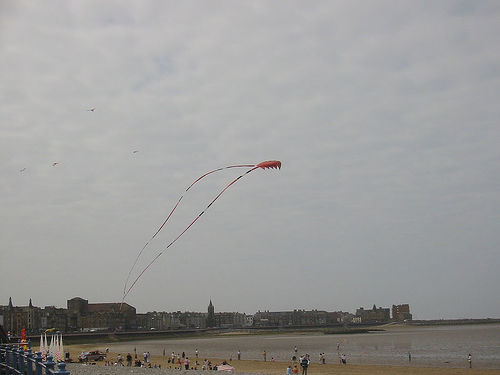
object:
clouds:
[0, 0, 500, 319]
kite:
[252, 158, 282, 172]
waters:
[83, 320, 500, 369]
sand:
[27, 340, 500, 375]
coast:
[0, 343, 499, 374]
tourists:
[181, 355, 190, 370]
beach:
[0, 341, 500, 375]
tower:
[204, 297, 218, 329]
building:
[389, 303, 413, 321]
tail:
[118, 163, 255, 311]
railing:
[0, 342, 74, 375]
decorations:
[38, 326, 67, 365]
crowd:
[75, 346, 236, 375]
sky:
[0, 0, 500, 320]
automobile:
[76, 348, 109, 363]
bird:
[132, 149, 140, 154]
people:
[235, 348, 242, 362]